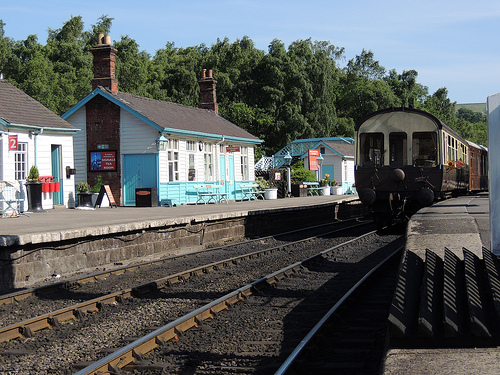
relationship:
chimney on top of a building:
[88, 31, 119, 94] [51, 30, 268, 211]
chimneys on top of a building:
[194, 64, 221, 117] [51, 30, 268, 211]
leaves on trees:
[178, 55, 337, 106] [0, 12, 490, 169]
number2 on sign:
[8, 138, 22, 149] [7, 131, 22, 153]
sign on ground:
[95, 184, 113, 203] [66, 201, 143, 229]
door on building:
[45, 139, 76, 206] [0, 68, 82, 213]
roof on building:
[114, 86, 255, 138] [61, 84, 263, 208]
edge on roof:
[157, 125, 269, 149] [102, 85, 259, 145]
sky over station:
[2, 0, 499, 107] [101, 91, 498, 333]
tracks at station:
[64, 264, 295, 356] [0, 1, 499, 371]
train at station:
[361, 108, 458, 228] [248, 155, 325, 205]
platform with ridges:
[388, 185, 496, 374] [391, 240, 499, 342]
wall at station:
[7, 202, 364, 288] [0, 91, 497, 375]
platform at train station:
[2, 192, 364, 297] [4, 0, 498, 370]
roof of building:
[0, 78, 70, 129] [2, 65, 82, 213]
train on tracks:
[353, 108, 488, 228] [285, 238, 407, 373]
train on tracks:
[353, 108, 488, 228] [79, 220, 400, 372]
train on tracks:
[353, 108, 488, 228] [2, 216, 355, 333]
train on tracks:
[353, 108, 488, 228] [9, 217, 344, 304]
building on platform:
[61, 84, 263, 208] [0, 177, 359, 252]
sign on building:
[87, 142, 120, 174] [51, 30, 268, 211]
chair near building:
[193, 184, 230, 205] [62, 73, 264, 198]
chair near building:
[204, 190, 220, 201] [62, 73, 264, 198]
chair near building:
[240, 183, 267, 202] [62, 73, 264, 198]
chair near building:
[247, 190, 257, 201] [62, 73, 264, 198]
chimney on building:
[85, 34, 121, 94] [61, 84, 263, 208]